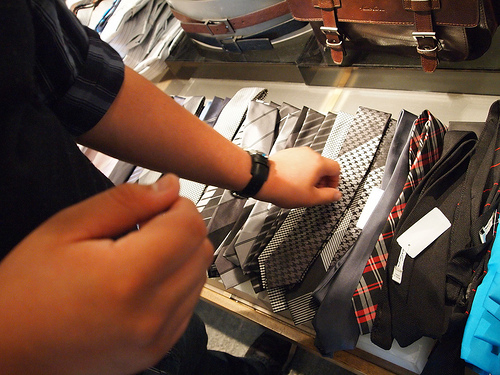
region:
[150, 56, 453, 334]
Many ties on a table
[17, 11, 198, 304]
Person is wearing a grey shirt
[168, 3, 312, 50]
The belt is brown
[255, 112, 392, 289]
The tie is black and grey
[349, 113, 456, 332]
The tie is red and black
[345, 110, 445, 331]
The tie is plaid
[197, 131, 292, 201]
Person is wearing a watch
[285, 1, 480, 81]
Brown bag on table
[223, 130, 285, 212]
The watch is black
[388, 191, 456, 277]
White tag attached to tie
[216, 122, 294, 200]
man is wearing a watch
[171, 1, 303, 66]
two belts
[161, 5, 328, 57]
brown belt and black belt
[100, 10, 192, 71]
pile of dress shirts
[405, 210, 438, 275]
price tag on the tie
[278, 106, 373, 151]
grey tie with white pen stripes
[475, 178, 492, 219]
black tie with red stripes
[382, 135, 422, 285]
tie is red, black and white plaid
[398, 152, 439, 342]
tie is black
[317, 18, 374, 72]
buckle on the bag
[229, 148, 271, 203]
a black wrist watch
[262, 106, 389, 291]
a spotted grey tie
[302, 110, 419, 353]
a solid grey tie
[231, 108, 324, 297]
a diagonally striped tie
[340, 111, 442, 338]
a red white and black tie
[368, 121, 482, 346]
a solid black tie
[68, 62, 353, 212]
a person's left arm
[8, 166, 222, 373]
a person's right hand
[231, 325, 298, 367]
a brown shoe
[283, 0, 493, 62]
a brown leather satchel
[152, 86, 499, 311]
the ties lined up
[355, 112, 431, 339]
the red and black plaid tie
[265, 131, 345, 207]
the hand touching the ties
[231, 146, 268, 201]
the black wrist watch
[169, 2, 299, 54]
the belts on display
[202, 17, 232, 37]
the buckle on the brown belt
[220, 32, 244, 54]
the buckle on the black belt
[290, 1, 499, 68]
the brown leather bag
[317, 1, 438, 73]
the straps on the brown bag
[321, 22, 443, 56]
the buckles on the brown bag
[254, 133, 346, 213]
the hand of a person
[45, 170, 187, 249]
the thumb of a person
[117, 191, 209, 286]
the finger of a person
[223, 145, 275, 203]
a black watch band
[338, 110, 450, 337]
a black and red plaid tie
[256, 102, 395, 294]
a black and gray tie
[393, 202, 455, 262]
a white tag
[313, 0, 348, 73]
a brown strap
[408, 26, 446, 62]
a metal buckle on the bag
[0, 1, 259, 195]
the arm of a man